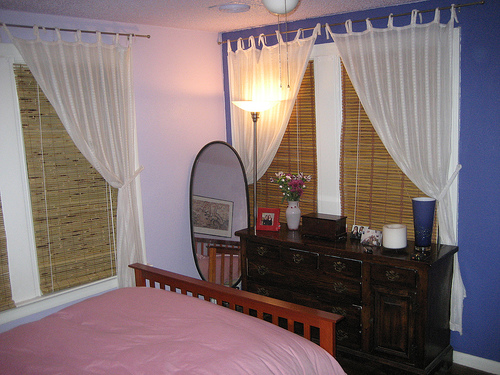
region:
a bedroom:
[8, 17, 452, 374]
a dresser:
[229, 185, 451, 359]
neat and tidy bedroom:
[6, 13, 493, 373]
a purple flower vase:
[409, 190, 436, 261]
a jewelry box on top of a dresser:
[298, 207, 350, 247]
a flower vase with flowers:
[273, 168, 303, 233]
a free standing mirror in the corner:
[184, 136, 256, 285]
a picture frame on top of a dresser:
[252, 200, 287, 235]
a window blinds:
[343, 111, 385, 211]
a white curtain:
[319, 14, 454, 194]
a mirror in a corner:
[188, 140, 248, 287]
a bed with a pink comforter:
[0, 264, 347, 374]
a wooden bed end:
[127, 263, 339, 359]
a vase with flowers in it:
[270, 171, 309, 230]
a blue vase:
[410, 194, 435, 251]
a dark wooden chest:
[243, 218, 452, 373]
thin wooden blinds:
[12, 63, 121, 292]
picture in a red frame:
[254, 206, 281, 229]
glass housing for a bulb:
[230, 99, 272, 113]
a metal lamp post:
[251, 113, 258, 229]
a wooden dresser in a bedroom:
[233, 218, 458, 373]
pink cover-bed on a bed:
[0, 278, 345, 373]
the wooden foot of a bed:
[127, 261, 342, 357]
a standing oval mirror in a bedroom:
[190, 137, 247, 289]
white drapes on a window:
[4, 20, 148, 289]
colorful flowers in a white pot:
[269, 166, 313, 232]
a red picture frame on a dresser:
[255, 208, 280, 233]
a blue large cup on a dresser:
[410, 196, 437, 247]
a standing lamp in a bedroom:
[232, 99, 277, 224]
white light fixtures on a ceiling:
[216, 0, 302, 17]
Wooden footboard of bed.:
[125, 252, 347, 350]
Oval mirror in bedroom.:
[185, 136, 252, 287]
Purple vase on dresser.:
[407, 191, 432, 246]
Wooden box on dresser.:
[295, 210, 342, 241]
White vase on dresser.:
[281, 197, 301, 228]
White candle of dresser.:
[380, 221, 405, 251]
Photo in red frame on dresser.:
[255, 205, 280, 231]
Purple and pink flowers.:
[270, 167, 310, 198]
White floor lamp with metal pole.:
[231, 85, 276, 231]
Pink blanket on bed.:
[3, 284, 350, 374]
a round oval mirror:
[188, 140, 248, 289]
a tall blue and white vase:
[414, 195, 437, 243]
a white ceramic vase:
[287, 196, 302, 233]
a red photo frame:
[258, 208, 278, 230]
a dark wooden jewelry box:
[302, 210, 344, 236]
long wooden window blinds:
[12, 60, 117, 285]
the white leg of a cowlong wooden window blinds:
[233, 57, 324, 231]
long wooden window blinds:
[340, 54, 437, 241]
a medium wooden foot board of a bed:
[128, 262, 340, 365]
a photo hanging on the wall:
[186, 190, 236, 237]